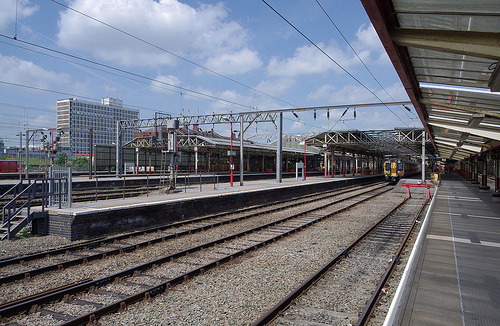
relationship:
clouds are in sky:
[55, 4, 264, 83] [6, 3, 404, 137]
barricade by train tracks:
[320, 159, 400, 179] [4, 178, 432, 325]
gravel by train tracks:
[202, 220, 358, 309] [4, 178, 432, 325]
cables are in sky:
[2, 1, 416, 136] [6, 3, 404, 137]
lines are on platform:
[436, 182, 499, 271] [386, 166, 500, 325]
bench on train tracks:
[399, 181, 440, 207] [4, 178, 432, 325]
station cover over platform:
[361, 2, 497, 164] [386, 166, 500, 325]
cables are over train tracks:
[2, 1, 416, 136] [4, 178, 432, 325]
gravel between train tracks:
[202, 220, 358, 309] [4, 178, 432, 325]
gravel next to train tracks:
[202, 220, 358, 309] [4, 178, 432, 325]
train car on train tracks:
[382, 154, 424, 185] [4, 178, 432, 325]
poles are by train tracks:
[222, 123, 314, 182] [4, 178, 432, 325]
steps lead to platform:
[0, 175, 57, 245] [38, 168, 342, 212]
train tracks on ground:
[4, 178, 432, 325] [293, 185, 415, 295]